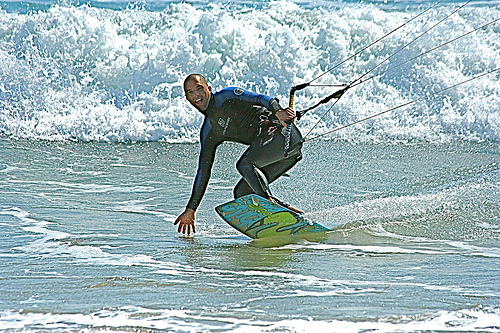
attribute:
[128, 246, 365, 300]
waves — small, white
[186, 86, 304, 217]
wet suit — blue, black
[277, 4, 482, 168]
cords — black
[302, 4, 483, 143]
lines — black, thin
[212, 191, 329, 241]
surfboard — blue, green, yellow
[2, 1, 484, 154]
waves — white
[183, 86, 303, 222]
body suit — blue, black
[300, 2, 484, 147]
reins — wired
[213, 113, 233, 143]
logo — white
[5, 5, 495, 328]
water — ocean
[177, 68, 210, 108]
head — man's, bald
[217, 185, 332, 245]
surfboard — blue, green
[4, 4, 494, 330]
surfing — wind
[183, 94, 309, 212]
suit — wet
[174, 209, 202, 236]
hand — man's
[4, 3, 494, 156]
wave — large, white, crashing, foaming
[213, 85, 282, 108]
fabric — blue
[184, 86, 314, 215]
suit — wet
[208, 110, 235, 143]
logo — company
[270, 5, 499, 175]
contraption — wind surfing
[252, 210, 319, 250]
s — green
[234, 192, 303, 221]
feet — man's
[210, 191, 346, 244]
surfboard — blue, green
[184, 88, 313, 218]
wetsuit — blue, black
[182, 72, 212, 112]
head — bald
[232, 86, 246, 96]
patch — white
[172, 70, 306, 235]
man — smiling, parasailing